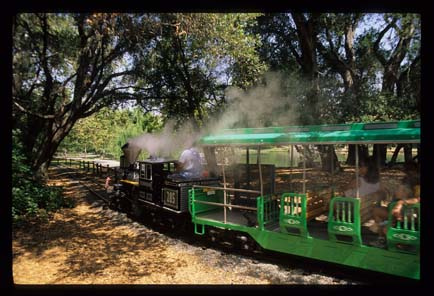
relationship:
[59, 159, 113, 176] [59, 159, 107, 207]
fence along train track